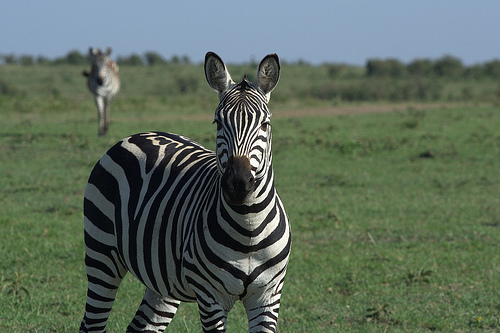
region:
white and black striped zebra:
[69, 62, 313, 325]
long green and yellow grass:
[309, 257, 371, 302]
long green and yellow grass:
[390, 253, 469, 314]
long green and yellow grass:
[16, 246, 64, 299]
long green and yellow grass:
[26, 181, 66, 222]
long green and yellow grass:
[21, 103, 57, 156]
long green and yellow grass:
[291, 119, 359, 173]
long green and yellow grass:
[342, 114, 412, 193]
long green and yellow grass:
[426, 120, 487, 177]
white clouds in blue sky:
[270, 8, 381, 52]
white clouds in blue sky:
[0, 4, 58, 50]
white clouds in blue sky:
[66, 8, 134, 44]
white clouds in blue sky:
[144, 7, 190, 49]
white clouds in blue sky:
[215, 11, 277, 44]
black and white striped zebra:
[131, 37, 318, 324]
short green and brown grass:
[288, 97, 358, 152]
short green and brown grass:
[301, 160, 388, 217]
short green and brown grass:
[317, 220, 370, 270]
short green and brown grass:
[315, 246, 365, 292]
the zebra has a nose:
[207, 152, 272, 204]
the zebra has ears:
[191, 46, 289, 98]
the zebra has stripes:
[94, 164, 199, 254]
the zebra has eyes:
[207, 108, 274, 133]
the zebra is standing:
[68, 48, 306, 325]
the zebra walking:
[80, 43, 125, 133]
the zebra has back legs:
[70, 268, 171, 328]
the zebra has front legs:
[180, 296, 301, 331]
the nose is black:
[213, 155, 256, 202]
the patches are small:
[347, 111, 446, 168]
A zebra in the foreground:
[64, 47, 306, 331]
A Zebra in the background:
[66, 32, 141, 137]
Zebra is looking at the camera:
[173, 40, 313, 215]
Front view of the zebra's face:
[181, 43, 311, 215]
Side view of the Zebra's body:
[56, 105, 207, 330]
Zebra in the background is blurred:
[68, 40, 127, 141]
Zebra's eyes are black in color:
[206, 109, 281, 143]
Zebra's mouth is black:
[216, 149, 263, 207]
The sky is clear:
[1, 1, 498, 66]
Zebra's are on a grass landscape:
[6, 67, 499, 330]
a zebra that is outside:
[37, 53, 467, 330]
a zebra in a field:
[51, 3, 458, 331]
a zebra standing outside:
[39, 37, 419, 332]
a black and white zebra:
[48, 23, 440, 323]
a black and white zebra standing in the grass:
[52, 39, 426, 331]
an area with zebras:
[50, 32, 442, 328]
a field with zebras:
[36, 14, 368, 328]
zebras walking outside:
[36, 21, 449, 326]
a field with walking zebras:
[21, 18, 437, 329]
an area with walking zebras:
[44, 37, 465, 329]